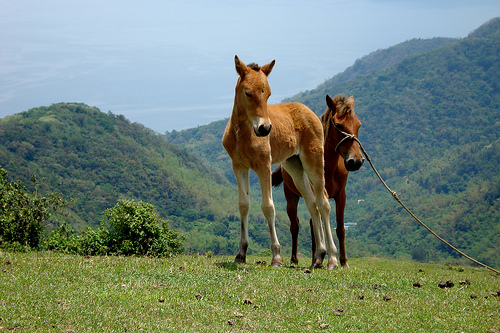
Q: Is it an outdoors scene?
A: Yes, it is outdoors.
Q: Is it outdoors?
A: Yes, it is outdoors.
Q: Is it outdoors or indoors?
A: It is outdoors.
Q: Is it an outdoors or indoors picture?
A: It is outdoors.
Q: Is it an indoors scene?
A: No, it is outdoors.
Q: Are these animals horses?
A: Yes, all the animals are horses.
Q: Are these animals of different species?
A: No, all the animals are horses.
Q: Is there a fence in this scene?
A: No, there are no fences.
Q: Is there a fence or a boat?
A: No, there are no fences or boats.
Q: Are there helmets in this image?
A: No, there are no helmets.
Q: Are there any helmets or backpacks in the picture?
A: No, there are no helmets or backpacks.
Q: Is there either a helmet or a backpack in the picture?
A: No, there are no helmets or backpacks.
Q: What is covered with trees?
A: The mountain side is covered with trees.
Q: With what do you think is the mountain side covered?
A: The mountain side is covered with trees.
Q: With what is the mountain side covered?
A: The mountain side is covered with trees.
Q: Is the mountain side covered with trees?
A: Yes, the mountain side is covered with trees.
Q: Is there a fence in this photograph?
A: No, there are no fences.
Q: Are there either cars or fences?
A: No, there are no fences or cars.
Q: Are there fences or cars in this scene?
A: No, there are no fences or cars.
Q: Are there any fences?
A: No, there are no fences.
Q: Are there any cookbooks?
A: No, there are no cookbooks.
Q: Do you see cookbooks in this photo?
A: No, there are no cookbooks.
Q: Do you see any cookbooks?
A: No, there are no cookbooks.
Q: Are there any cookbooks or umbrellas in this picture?
A: No, there are no cookbooks or umbrellas.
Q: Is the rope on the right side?
A: Yes, the rope is on the right of the image.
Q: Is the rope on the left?
A: No, the rope is on the right of the image.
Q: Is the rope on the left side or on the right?
A: The rope is on the right of the image.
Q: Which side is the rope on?
A: The rope is on the right of the image.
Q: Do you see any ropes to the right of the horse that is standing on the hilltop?
A: Yes, there is a rope to the right of the horse.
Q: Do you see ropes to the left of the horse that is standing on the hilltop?
A: No, the rope is to the right of the horse.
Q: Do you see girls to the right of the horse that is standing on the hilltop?
A: No, there is a rope to the right of the horse.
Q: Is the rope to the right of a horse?
A: Yes, the rope is to the right of a horse.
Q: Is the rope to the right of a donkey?
A: No, the rope is to the right of a horse.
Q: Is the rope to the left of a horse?
A: No, the rope is to the right of a horse.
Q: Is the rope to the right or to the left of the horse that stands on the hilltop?
A: The rope is to the right of the horse.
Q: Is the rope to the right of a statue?
A: No, the rope is to the right of a horse.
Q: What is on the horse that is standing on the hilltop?
A: The rope is on the horse.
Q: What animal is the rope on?
A: The rope is on the horse.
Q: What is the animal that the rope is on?
A: The animal is a horse.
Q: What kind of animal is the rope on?
A: The rope is on the horse.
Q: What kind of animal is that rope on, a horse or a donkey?
A: The rope is on a horse.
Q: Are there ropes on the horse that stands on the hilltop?
A: Yes, there is a rope on the horse.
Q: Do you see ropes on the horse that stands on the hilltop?
A: Yes, there is a rope on the horse.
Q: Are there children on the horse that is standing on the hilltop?
A: No, there is a rope on the horse.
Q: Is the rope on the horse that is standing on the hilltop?
A: Yes, the rope is on the horse.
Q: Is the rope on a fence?
A: No, the rope is on the horse.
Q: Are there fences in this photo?
A: No, there are no fences.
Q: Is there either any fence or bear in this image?
A: No, there are no fences or bears.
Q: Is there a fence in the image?
A: No, there are no fences.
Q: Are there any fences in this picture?
A: No, there are no fences.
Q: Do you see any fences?
A: No, there are no fences.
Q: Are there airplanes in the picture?
A: No, there are no airplanes.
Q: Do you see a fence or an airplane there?
A: No, there are no airplanes or fences.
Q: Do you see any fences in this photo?
A: No, there are no fences.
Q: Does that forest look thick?
A: Yes, the forest is thick.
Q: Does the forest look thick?
A: Yes, the forest is thick.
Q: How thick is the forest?
A: The forest is thick.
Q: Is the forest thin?
A: No, the forest is thick.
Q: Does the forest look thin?
A: No, the forest is thick.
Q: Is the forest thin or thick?
A: The forest is thick.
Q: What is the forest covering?
A: The forest is covering the mountain.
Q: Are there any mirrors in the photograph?
A: No, there are no mirrors.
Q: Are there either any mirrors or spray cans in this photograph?
A: No, there are no mirrors or spray cans.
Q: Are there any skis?
A: No, there are no skis.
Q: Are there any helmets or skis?
A: No, there are no skis or helmets.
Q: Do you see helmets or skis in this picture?
A: No, there are no skis or helmets.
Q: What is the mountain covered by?
A: The mountain is covered by the forest.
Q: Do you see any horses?
A: Yes, there is a horse.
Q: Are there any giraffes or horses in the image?
A: Yes, there is a horse.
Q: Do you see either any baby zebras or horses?
A: Yes, there is a baby horse.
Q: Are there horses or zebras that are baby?
A: Yes, the horse is a baby.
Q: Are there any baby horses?
A: Yes, there is a baby horse.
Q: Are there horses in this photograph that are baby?
A: Yes, there is a horse that is a baby.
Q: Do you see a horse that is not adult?
A: Yes, there is an baby horse.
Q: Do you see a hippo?
A: No, there are no hippos.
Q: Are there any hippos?
A: No, there are no hippos.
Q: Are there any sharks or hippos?
A: No, there are no hippos or sharks.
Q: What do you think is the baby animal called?
A: The animal is a horse.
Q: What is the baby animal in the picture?
A: The animal is a horse.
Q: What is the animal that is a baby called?
A: The animal is a horse.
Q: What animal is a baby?
A: The animal is a horse.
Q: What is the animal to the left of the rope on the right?
A: The animal is a horse.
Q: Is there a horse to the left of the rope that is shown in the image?
A: Yes, there is a horse to the left of the rope.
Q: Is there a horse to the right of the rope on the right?
A: No, the horse is to the left of the rope.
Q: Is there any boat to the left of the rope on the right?
A: No, there is a horse to the left of the rope.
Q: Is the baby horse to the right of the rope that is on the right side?
A: No, the horse is to the left of the rope.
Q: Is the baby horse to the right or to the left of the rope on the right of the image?
A: The horse is to the left of the rope.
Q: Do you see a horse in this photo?
A: Yes, there is a horse.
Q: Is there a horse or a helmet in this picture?
A: Yes, there is a horse.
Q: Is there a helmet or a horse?
A: Yes, there is a horse.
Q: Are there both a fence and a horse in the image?
A: No, there is a horse but no fences.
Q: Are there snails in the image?
A: No, there are no snails.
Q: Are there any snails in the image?
A: No, there are no snails.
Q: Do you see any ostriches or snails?
A: No, there are no snails or ostriches.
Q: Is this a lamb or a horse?
A: This is a horse.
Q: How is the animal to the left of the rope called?
A: The animal is a horse.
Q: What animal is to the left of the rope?
A: The animal is a horse.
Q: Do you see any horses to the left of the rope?
A: Yes, there is a horse to the left of the rope.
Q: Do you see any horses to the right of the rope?
A: No, the horse is to the left of the rope.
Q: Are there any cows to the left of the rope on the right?
A: No, there is a horse to the left of the rope.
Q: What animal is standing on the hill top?
A: The horse is standing on the hill top.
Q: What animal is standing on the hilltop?
A: The horse is standing on the hill top.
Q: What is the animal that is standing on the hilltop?
A: The animal is a horse.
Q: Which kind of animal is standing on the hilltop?
A: The animal is a horse.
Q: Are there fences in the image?
A: No, there are no fences.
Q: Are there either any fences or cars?
A: No, there are no fences or cars.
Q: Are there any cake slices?
A: No, there are no cake slices.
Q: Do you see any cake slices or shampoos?
A: No, there are no cake slices or shampoos.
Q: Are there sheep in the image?
A: No, there are no sheep.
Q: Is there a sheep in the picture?
A: No, there is no sheep.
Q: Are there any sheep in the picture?
A: No, there are no sheep.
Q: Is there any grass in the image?
A: Yes, there is grass.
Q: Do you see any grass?
A: Yes, there is grass.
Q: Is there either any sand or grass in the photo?
A: Yes, there is grass.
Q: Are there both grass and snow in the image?
A: No, there is grass but no snow.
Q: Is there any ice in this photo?
A: No, there is no ice.